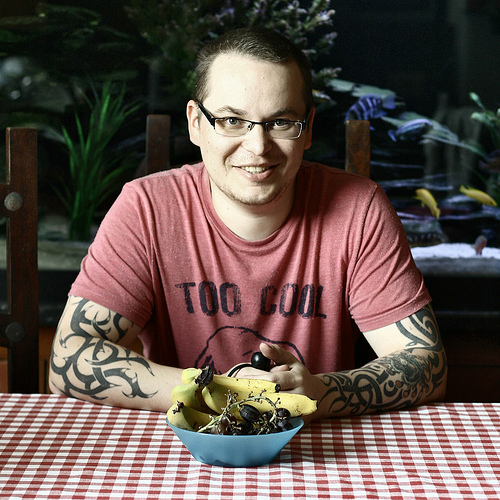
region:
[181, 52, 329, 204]
a man wearing glasses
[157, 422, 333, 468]
a blue plastic bowl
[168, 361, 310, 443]
yellow bananas and grapes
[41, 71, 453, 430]
a man with tatoos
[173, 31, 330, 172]
a man with short hair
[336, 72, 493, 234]
fish in a aqarium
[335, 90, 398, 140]
a purple and black fish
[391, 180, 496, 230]
two yellow fish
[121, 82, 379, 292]
a man wearing a red shirt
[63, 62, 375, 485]
a man sitting at a table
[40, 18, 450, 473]
The man is sitting at a table.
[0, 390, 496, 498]
A red and white checkered table cloth.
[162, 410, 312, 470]
The bowl is blue.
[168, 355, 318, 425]
Bananas are in the bowl.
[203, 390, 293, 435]
Grapes are in the bowl.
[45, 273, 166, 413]
The man has tattoos on his arm.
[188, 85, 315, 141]
The man is wearing glasses.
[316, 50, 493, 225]
Fish are swimming in a tank.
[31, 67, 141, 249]
A small green plant in the background.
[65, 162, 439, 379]
The man is wearing a red t-shirt.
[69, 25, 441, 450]
Man sitting at a table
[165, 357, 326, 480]
Bowl of fruit on the table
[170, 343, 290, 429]
Bunch of yellow bananas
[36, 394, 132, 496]
Table cloth is red and white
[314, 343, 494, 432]
Man has tattoo on arm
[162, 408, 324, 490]
The bowl is blue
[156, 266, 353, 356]
The tshirt says too cool on it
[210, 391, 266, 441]
Stem holding the grapes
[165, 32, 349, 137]
Man has short hair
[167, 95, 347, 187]
man is wearing glasses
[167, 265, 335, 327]
Black letters on shirt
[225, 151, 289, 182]
Big lucious pink lips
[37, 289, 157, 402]
Black tribal tattoo on arm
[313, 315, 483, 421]
Black tribal tattoo on arm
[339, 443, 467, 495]
REd and white checkered tablecloth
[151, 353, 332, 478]
Fruit in a bowl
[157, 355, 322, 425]
Yellow fruit in a blue bowl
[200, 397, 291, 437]
Red grapes in a bowl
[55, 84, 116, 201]
Birght green grass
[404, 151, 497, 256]
Yellow fish swimming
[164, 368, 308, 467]
A bowl of fruit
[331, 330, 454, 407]
Tatoos on a person's arm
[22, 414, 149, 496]
The tablecloth is checkered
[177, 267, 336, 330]
Lettering on a red shirt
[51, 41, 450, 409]
A person sits at a table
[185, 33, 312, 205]
The man is wearing glasses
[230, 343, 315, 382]
Person is holding black object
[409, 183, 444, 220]
Yellow fish in the tank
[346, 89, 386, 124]
A striped blue fish swims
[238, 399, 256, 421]
A single purple grape